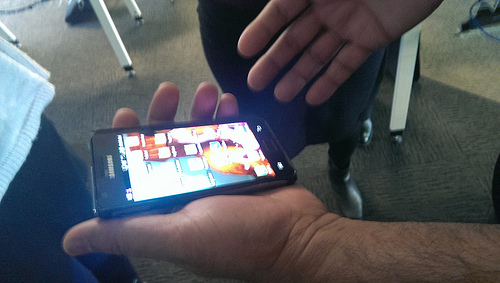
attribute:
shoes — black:
[329, 151, 363, 211]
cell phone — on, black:
[70, 87, 341, 217]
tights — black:
[308, 116, 362, 179]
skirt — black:
[174, 14, 372, 141]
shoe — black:
[323, 148, 359, 216]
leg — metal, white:
[361, 28, 430, 150]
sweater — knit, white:
[3, 29, 48, 204]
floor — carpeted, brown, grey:
[11, 16, 432, 186]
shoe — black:
[29, 5, 113, 29]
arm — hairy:
[259, 195, 490, 283]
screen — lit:
[117, 114, 243, 204]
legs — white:
[8, 5, 168, 78]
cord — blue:
[431, 8, 492, 60]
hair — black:
[315, 230, 459, 269]